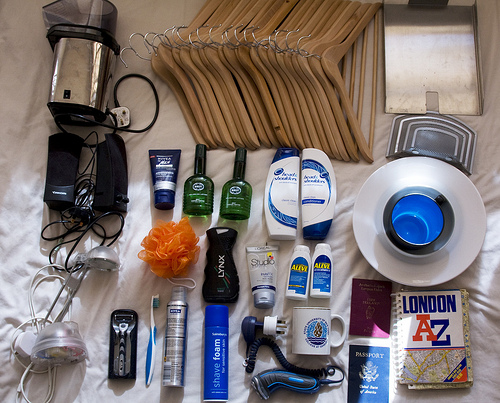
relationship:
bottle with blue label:
[285, 245, 311, 301] [290, 256, 307, 292]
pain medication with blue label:
[309, 243, 333, 299] [314, 256, 330, 289]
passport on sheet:
[346, 345, 391, 402] [0, 0, 500, 403]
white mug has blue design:
[290, 304, 347, 360] [303, 314, 331, 349]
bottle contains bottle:
[285, 245, 311, 303] [309, 241, 334, 299]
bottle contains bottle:
[308, 241, 334, 298] [309, 241, 334, 299]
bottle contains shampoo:
[201, 225, 240, 307] [202, 226, 241, 304]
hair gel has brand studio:
[241, 249, 283, 306] [248, 248, 279, 266]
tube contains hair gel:
[243, 246, 283, 309] [241, 249, 283, 306]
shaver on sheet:
[249, 367, 325, 401] [0, 6, 497, 401]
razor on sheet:
[108, 310, 140, 375] [0, 6, 497, 401]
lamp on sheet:
[29, 249, 121, 368] [2, 121, 39, 270]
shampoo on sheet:
[188, 211, 250, 311] [0, 0, 500, 403]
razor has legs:
[30, 0, 139, 278] [241, 364, 342, 396]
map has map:
[389, 287, 475, 391] [389, 287, 478, 392]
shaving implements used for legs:
[240, 310, 345, 401] [240, 314, 345, 400]